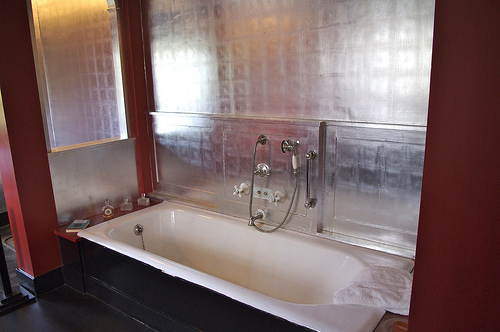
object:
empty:
[171, 225, 311, 284]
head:
[277, 137, 298, 154]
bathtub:
[66, 199, 414, 332]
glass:
[143, 0, 434, 260]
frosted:
[141, 0, 434, 262]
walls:
[0, 0, 159, 296]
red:
[14, 228, 41, 267]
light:
[150, 34, 217, 170]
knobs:
[250, 161, 272, 180]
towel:
[331, 264, 413, 316]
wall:
[145, 1, 435, 257]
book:
[64, 219, 89, 232]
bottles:
[135, 191, 152, 208]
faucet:
[247, 208, 265, 225]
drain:
[131, 223, 148, 252]